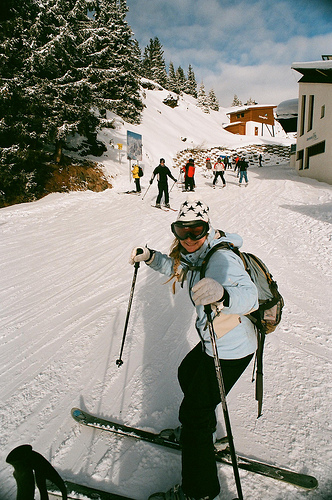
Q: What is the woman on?
A: Skis.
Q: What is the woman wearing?
A: Blue coat.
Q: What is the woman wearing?
A: Black pants.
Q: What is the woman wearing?
A: Backpack.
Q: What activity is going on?
A: Skiing.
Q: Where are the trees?
A: Left.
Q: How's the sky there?
A: Cloudy.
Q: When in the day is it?
A: Afternoon.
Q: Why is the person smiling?
A: She is happy.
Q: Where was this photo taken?
A: A mountain.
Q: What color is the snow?
A: White.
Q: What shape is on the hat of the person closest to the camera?
A: Star.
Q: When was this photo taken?
A: Day time.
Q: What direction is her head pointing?
A: Toward the camera.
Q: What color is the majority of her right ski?
A: Green.